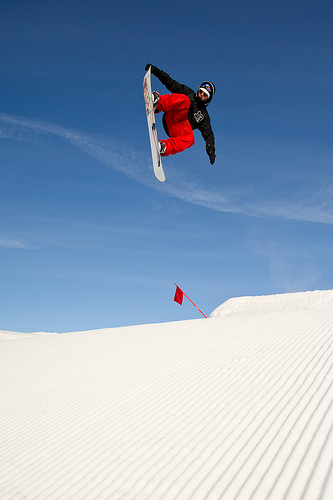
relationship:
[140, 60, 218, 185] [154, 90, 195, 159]
man wearing pants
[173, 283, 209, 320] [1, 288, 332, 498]
flag in snow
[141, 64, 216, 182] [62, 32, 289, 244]
snowboarder floating through air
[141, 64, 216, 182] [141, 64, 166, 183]
snowboarder on board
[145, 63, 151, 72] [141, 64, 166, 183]
hand on board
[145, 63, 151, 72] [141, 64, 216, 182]
hand of snowboarder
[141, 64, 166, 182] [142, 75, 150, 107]
snowboard has design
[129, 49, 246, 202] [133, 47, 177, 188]
man on snowboard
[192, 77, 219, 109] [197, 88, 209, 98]
head with sunglasses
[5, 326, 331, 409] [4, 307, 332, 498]
snow with grooves